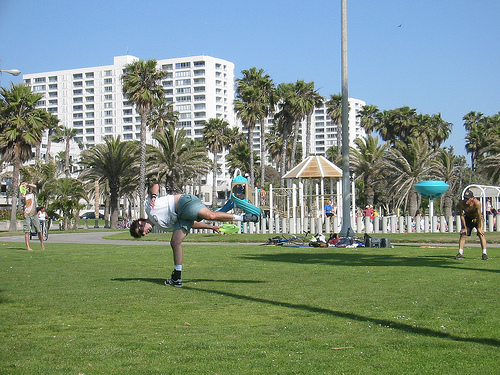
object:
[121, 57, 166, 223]
tree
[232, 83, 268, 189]
tree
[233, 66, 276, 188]
tree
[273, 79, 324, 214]
tree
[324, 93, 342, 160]
tree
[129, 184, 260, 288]
man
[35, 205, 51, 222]
woman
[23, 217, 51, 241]
bicycle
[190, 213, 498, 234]
fence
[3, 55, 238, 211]
building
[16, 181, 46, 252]
man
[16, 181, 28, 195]
frisbee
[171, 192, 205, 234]
shorts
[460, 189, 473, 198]
baseball cap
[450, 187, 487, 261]
guy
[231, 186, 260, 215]
slide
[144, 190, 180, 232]
shirt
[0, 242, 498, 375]
playground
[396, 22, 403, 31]
bird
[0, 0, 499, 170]
sky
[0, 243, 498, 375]
field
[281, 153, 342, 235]
gazebo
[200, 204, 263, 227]
kick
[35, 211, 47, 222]
shirt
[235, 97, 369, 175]
hotel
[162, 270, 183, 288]
shoe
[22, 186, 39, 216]
shirt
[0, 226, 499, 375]
ground